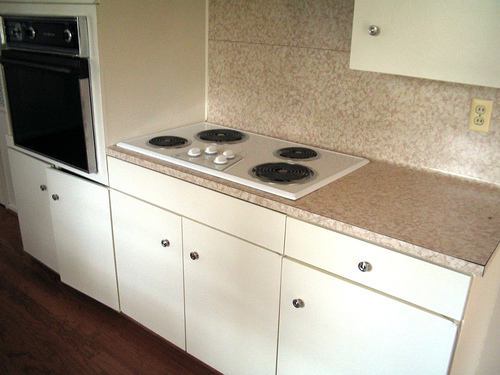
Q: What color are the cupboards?
A: White.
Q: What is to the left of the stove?
A: An oven.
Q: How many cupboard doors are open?
A: One.